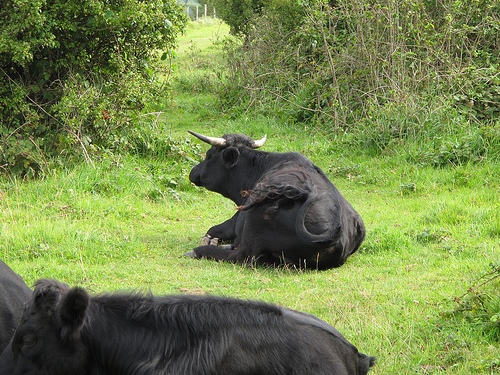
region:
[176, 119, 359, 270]
large black bull lying down with back to camera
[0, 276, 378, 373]
part of another lying down cow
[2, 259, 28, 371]
very small part of a third cow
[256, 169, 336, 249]
bulls tail curled up unto its side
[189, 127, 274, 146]
two sharp dangerous horns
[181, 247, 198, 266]
hoof of cows back leg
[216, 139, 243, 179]
black funnle shaped ear of bull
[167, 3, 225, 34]
wood post and barbed wire fence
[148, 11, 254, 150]
tunnel like space between two areas filled with brush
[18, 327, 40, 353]
the eyeball of a lying down cow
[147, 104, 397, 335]
a cow sitting in grass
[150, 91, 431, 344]
a cow sitting in field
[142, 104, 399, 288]
a cow sitting in forest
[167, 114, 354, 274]
a cow sitting in desert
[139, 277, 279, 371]
a fur of the cow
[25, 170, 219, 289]
a green grass in the forest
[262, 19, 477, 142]
a view of green grass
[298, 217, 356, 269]
tail of the cow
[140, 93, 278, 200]
face of the cow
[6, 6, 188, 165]
a part of the trees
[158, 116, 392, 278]
A bull resting on grass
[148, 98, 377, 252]
large black cow in grass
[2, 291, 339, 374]
large black cow in grass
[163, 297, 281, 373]
long black fur on cow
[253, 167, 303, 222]
long black fur on cow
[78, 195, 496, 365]
green grass under cows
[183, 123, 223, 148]
large horn of cow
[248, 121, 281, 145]
large horn of cow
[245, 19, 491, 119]
thick bushes around cows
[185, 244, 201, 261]
gray hoof of cow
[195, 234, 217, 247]
gray hoof of cow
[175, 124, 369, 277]
large black bull lying in the grass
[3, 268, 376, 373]
large black cow lying in the grass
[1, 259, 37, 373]
back end of cow lying in the grass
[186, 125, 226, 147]
black bulls left horn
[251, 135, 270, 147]
black bulls right horn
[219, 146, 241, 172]
black bulls left ear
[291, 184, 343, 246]
black bulls long tail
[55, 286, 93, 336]
cow lying in grass right ear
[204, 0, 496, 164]
large over grown shrubbery growing in the pasture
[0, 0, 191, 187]
large over grown shrubbery in cow pasture